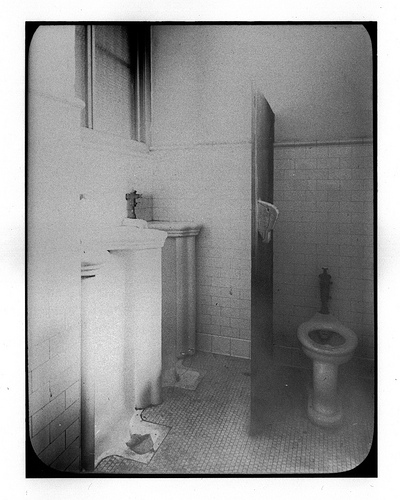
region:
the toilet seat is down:
[281, 297, 359, 383]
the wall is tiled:
[168, 185, 205, 209]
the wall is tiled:
[271, 184, 327, 240]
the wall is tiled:
[287, 185, 352, 269]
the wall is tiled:
[192, 163, 230, 249]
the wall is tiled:
[287, 163, 333, 238]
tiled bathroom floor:
[82, 348, 371, 470]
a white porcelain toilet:
[293, 304, 357, 428]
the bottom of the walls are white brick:
[25, 137, 371, 469]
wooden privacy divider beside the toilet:
[247, 83, 272, 437]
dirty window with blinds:
[83, 25, 151, 151]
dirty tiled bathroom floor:
[88, 350, 376, 471]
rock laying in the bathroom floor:
[124, 429, 160, 459]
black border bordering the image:
[26, 20, 379, 478]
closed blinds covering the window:
[88, 23, 140, 141]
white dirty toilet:
[295, 264, 357, 430]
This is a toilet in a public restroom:
[290, 272, 353, 402]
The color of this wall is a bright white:
[184, 49, 220, 118]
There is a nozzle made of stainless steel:
[122, 179, 150, 225]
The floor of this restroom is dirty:
[195, 425, 226, 459]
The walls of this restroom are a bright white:
[44, 249, 56, 345]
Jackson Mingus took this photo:
[102, 80, 307, 404]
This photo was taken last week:
[108, 70, 283, 451]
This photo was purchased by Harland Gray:
[101, 71, 342, 440]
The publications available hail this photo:
[88, 80, 339, 445]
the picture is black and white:
[33, 40, 366, 456]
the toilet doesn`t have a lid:
[266, 240, 355, 442]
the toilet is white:
[276, 281, 356, 439]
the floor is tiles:
[154, 386, 326, 469]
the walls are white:
[267, 124, 363, 344]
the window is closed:
[44, 22, 160, 165]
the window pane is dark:
[47, 20, 168, 154]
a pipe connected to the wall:
[300, 255, 347, 312]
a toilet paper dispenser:
[246, 180, 289, 270]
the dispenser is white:
[230, 172, 295, 261]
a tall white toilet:
[285, 301, 362, 436]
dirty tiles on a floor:
[172, 409, 248, 463]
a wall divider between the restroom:
[249, 189, 291, 429]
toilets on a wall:
[96, 219, 159, 465]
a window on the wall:
[75, 28, 173, 140]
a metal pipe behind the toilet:
[314, 260, 333, 316]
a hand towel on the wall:
[254, 193, 283, 249]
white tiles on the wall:
[41, 256, 87, 457]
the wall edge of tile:
[282, 130, 378, 153]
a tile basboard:
[193, 329, 259, 363]